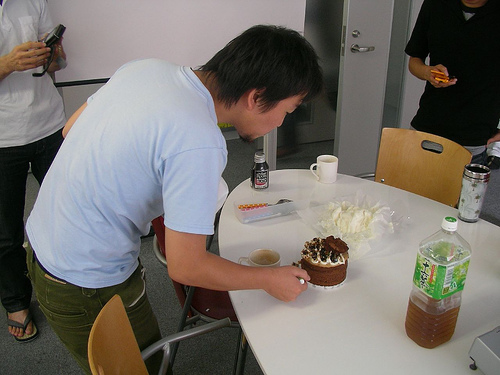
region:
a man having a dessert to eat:
[16, 12, 357, 364]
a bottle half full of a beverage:
[402, 211, 477, 358]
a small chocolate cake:
[296, 232, 356, 297]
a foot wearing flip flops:
[0, 302, 42, 345]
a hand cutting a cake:
[259, 229, 361, 314]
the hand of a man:
[421, 56, 461, 98]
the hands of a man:
[6, 23, 73, 83]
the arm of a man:
[161, 165, 311, 318]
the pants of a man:
[24, 229, 160, 374]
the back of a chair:
[372, 120, 474, 222]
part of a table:
[426, 243, 436, 253]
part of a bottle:
[441, 268, 442, 277]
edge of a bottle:
[298, 335, 319, 352]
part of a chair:
[197, 335, 201, 346]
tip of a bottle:
[435, 235, 442, 247]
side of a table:
[291, 335, 296, 340]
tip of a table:
[319, 296, 321, 305]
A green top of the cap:
[443, 212, 459, 223]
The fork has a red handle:
[233, 196, 300, 213]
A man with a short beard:
[205, 12, 332, 147]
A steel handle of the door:
[347, 42, 387, 57]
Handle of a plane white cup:
[305, 161, 322, 179]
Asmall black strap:
[23, 62, 60, 83]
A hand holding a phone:
[413, 59, 463, 97]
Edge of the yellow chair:
[96, 287, 133, 309]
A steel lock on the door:
[348, 27, 375, 39]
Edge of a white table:
[236, 321, 273, 373]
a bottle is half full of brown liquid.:
[405, 215, 472, 353]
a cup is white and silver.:
[456, 165, 488, 221]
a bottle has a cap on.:
[248, 152, 272, 189]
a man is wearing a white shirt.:
[23, 57, 228, 289]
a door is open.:
[281, 0, 396, 176]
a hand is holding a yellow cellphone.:
[423, 62, 460, 87]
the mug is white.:
[309, 152, 342, 184]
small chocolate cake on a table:
[297, 227, 353, 292]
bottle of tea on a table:
[404, 191, 475, 359]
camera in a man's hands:
[26, 15, 78, 81]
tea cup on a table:
[235, 242, 286, 272]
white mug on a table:
[312, 152, 342, 188]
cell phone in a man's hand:
[425, 56, 456, 93]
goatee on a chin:
[237, 127, 259, 146]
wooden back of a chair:
[108, 313, 130, 348]